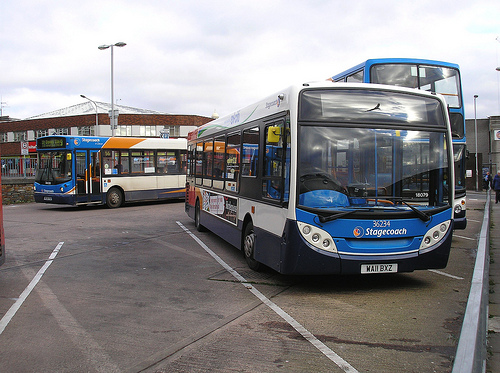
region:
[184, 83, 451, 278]
blue and white bus in front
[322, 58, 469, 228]
two story bus behind the front bus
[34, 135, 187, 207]
blue, orange, and white bus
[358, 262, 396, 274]
white license plate on the bus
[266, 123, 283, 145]
passenger side mirror on the bus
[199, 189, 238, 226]
advertisement on the side of the bus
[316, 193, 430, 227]
black windshield wipers on the bus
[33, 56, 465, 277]
three buses parked in a parking lot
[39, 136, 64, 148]
route on the front of the bus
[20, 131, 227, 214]
This is a bus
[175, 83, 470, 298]
This is a bus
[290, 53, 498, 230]
This is a bus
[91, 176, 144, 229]
Wheel of a bus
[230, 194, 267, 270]
Wheel of a bus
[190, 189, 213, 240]
Wheel of a bus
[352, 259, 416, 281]
bus registration number plate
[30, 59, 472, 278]
buses in a lot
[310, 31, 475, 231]
double decker bus in lot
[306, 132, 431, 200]
window of the bus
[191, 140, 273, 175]
window on side of bus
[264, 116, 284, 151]
mirror on the bus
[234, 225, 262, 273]
wheel on the bus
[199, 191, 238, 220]
advertisement on the bus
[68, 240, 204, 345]
space for parking vehicle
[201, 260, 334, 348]
white line on lot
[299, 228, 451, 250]
light on the bus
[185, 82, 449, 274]
blue white and orange bus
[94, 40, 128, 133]
metal parking lot pole with two outdoor light fixtures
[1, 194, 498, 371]
white striping on parking lot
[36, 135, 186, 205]
single decker blue orange and white bus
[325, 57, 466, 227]
double decker bus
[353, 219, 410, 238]
bus number and manufacturer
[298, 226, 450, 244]
bus headlights and turn signals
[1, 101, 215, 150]
building with pagoda style roof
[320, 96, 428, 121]
unlit bus front destination sign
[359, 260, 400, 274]
bus front license plate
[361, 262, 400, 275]
license plate of the bus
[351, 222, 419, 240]
name of the maker of the bus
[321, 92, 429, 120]
board showing the destination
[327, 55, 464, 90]
double decker bus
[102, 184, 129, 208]
wheels of the bus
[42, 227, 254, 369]
parking slot for the bus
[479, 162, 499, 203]
people waiting for the bus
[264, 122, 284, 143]
rear view mirrror of the bus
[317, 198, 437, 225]
windshield wipers on the bus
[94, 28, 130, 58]
night lights for the street